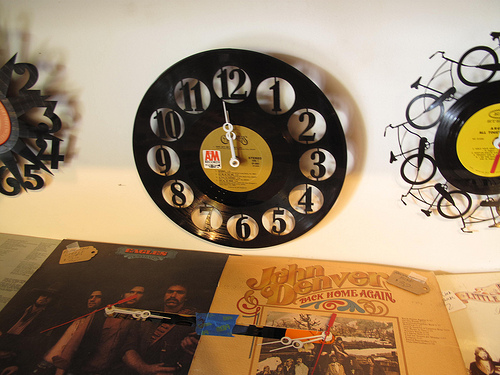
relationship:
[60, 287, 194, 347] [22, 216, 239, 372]
eagle on album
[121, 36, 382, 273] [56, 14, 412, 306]
clock on wall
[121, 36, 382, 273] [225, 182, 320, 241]
clock with numbers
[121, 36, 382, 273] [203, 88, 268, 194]
clock with arms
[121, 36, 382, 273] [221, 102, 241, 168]
clock has arms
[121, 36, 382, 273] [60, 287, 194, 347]
clock with eagle